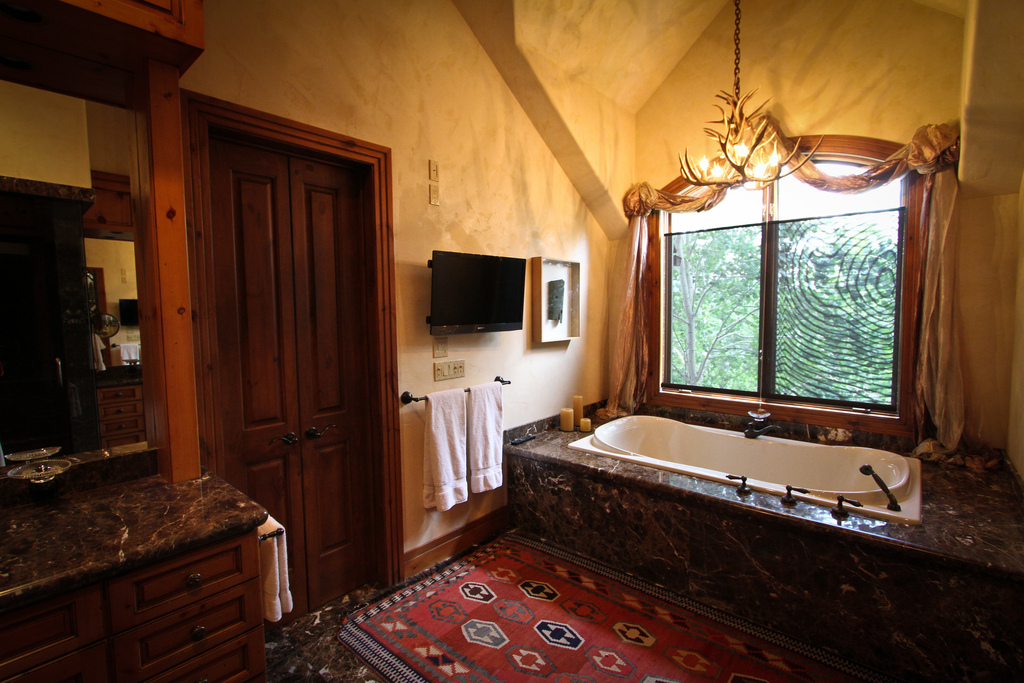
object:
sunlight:
[662, 163, 905, 406]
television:
[425, 250, 524, 336]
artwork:
[532, 257, 581, 344]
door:
[180, 91, 404, 642]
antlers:
[622, 84, 959, 217]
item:
[548, 280, 564, 325]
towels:
[424, 381, 506, 512]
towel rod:
[402, 376, 512, 404]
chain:
[733, 4, 742, 100]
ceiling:
[514, 1, 969, 113]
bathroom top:
[0, 465, 269, 610]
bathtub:
[569, 415, 922, 525]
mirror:
[0, 78, 143, 380]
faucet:
[859, 464, 902, 511]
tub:
[594, 415, 912, 524]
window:
[646, 134, 926, 439]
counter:
[503, 406, 1024, 683]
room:
[0, 0, 1024, 683]